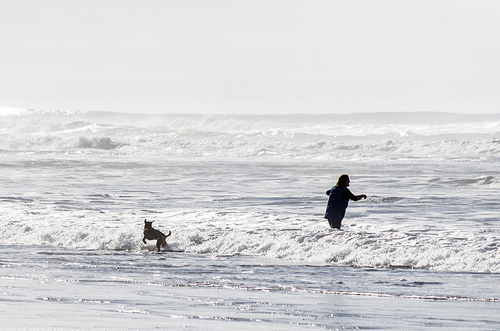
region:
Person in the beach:
[316, 162, 373, 239]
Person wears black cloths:
[311, 167, 374, 239]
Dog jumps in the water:
[129, 211, 180, 261]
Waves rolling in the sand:
[4, 202, 496, 274]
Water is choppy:
[0, 100, 499, 170]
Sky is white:
[2, 1, 496, 108]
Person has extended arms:
[311, 162, 371, 232]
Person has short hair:
[317, 166, 370, 236]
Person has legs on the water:
[321, 168, 376, 240]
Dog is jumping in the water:
[131, 213, 178, 256]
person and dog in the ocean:
[105, 152, 383, 275]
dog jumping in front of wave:
[135, 211, 187, 261]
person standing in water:
[305, 155, 385, 237]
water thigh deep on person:
[291, 141, 371, 241]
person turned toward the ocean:
[315, 160, 380, 245]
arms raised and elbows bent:
[310, 155, 395, 235]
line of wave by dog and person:
[35, 170, 460, 270]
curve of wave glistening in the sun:
[1, 100, 72, 135]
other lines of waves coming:
[155, 100, 481, 175]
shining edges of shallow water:
[37, 246, 377, 327]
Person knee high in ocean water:
[321, 169, 368, 231]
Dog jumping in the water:
[141, 216, 175, 253]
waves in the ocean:
[211, 211, 291, 256]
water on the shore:
[25, 270, 166, 320]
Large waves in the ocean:
[10, 107, 145, 172]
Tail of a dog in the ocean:
[165, 227, 175, 241]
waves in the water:
[210, 218, 282, 255]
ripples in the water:
[175, 168, 230, 195]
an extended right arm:
[348, 187, 366, 201]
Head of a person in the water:
[334, 172, 353, 189]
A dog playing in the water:
[140, 218, 172, 250]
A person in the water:
[327, 174, 365, 231]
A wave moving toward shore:
[0, 202, 498, 274]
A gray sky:
[1, 0, 494, 112]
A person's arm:
[346, 189, 366, 201]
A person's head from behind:
[335, 171, 350, 188]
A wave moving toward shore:
[0, 105, 490, 126]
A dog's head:
[140, 216, 150, 226]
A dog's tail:
[160, 225, 170, 235]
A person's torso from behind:
[325, 185, 346, 217]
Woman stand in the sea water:
[315, 163, 371, 239]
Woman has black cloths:
[310, 165, 370, 236]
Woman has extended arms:
[314, 167, 376, 235]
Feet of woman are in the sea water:
[313, 167, 371, 235]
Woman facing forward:
[316, 164, 373, 234]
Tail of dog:
[162, 225, 174, 240]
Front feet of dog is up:
[136, 234, 153, 247]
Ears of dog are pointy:
[136, 213, 161, 225]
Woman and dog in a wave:
[0, 164, 499, 268]